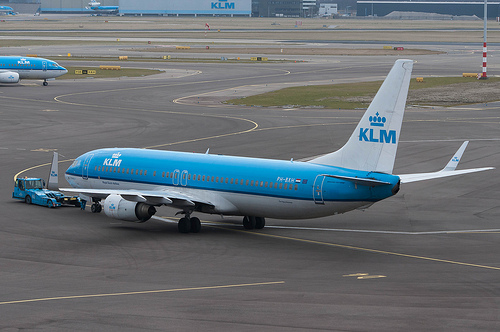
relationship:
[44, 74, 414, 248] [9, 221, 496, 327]
plane on top of tarmac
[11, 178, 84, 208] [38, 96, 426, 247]
car in front of plane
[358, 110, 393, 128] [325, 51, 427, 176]
logo printed on tail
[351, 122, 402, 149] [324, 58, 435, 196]
letters are printed on tail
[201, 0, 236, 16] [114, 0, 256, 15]
letters are printed on sign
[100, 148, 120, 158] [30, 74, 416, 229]
logo printed on plane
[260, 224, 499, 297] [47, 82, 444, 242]
line underneath plane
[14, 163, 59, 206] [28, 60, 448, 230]
car in front of plane